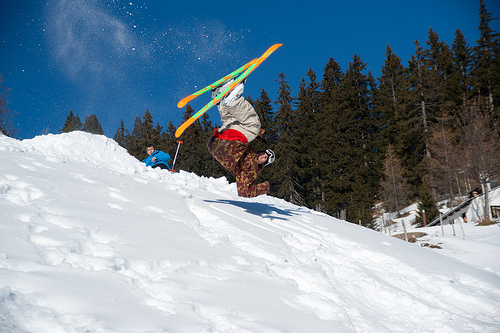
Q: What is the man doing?
A: Skiing.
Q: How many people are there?
A: Two.